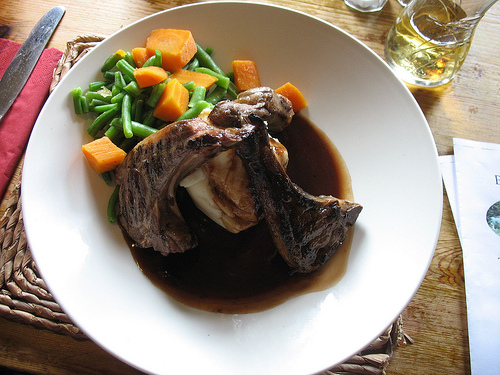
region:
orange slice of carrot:
[142, 22, 206, 64]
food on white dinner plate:
[27, 3, 450, 365]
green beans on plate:
[105, 90, 142, 135]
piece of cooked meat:
[123, 91, 361, 303]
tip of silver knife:
[4, 8, 64, 86]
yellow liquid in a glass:
[400, 5, 470, 89]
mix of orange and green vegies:
[70, 28, 279, 161]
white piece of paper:
[446, 130, 498, 330]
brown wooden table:
[420, 293, 459, 367]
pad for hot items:
[2, 227, 31, 312]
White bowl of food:
[21, 1, 444, 373]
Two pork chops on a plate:
[113, 85, 365, 270]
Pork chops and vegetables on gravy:
[67, 25, 360, 276]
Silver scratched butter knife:
[1, 3, 65, 127]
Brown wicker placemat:
[0, 33, 402, 373]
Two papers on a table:
[437, 133, 498, 373]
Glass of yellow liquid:
[387, 0, 499, 87]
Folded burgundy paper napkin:
[1, 33, 61, 213]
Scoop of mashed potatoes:
[184, 125, 288, 239]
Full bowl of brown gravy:
[118, 95, 350, 319]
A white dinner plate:
[22, 0, 444, 374]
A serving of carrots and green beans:
[70, 27, 307, 222]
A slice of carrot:
[147, 25, 196, 66]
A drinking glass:
[384, 1, 499, 86]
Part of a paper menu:
[440, 137, 499, 374]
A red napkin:
[1, 36, 62, 202]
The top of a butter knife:
[0, 8, 65, 118]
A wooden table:
[0, 1, 498, 373]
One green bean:
[121, 94, 136, 138]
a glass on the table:
[391, 3, 474, 85]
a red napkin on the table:
[7, 28, 47, 165]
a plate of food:
[46, 17, 430, 355]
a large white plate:
[34, 20, 429, 368]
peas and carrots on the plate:
[82, 32, 219, 130]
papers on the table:
[453, 126, 499, 305]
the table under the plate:
[418, 298, 466, 369]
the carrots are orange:
[164, 34, 179, 53]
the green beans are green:
[103, 83, 135, 111]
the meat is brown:
[153, 207, 181, 234]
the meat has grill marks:
[142, 147, 168, 172]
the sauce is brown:
[216, 257, 252, 283]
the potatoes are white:
[188, 182, 205, 202]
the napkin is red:
[23, 89, 38, 113]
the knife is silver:
[12, 45, 39, 77]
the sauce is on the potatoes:
[215, 174, 238, 197]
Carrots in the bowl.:
[145, 30, 230, 120]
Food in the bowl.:
[95, 60, 359, 283]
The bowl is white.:
[8, 88, 455, 345]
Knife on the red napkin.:
[11, 21, 66, 103]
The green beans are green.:
[85, 74, 145, 127]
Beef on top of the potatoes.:
[143, 113, 328, 256]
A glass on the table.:
[401, 10, 471, 90]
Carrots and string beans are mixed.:
[92, 43, 256, 115]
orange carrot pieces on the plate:
[89, 27, 314, 168]